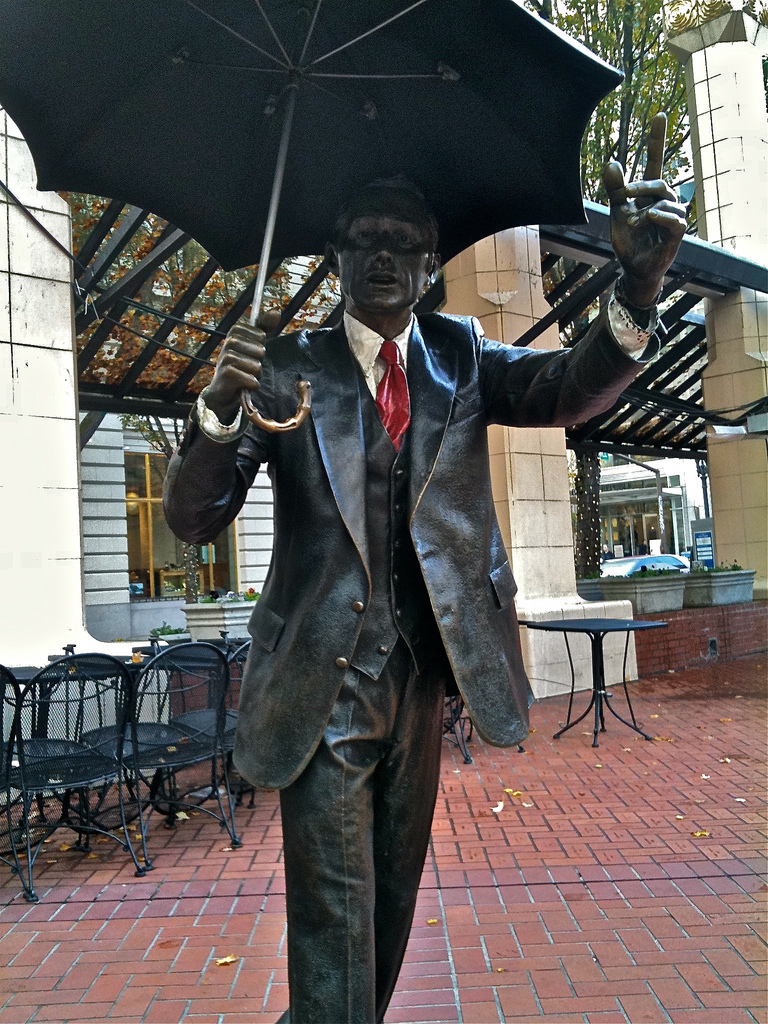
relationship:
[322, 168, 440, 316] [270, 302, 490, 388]
head above shoulder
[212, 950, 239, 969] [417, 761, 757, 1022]
leaf on ground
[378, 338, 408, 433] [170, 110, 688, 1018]
tie on statue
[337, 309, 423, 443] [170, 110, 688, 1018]
dress shirt painted on statue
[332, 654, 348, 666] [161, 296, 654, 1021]
button of dress shirt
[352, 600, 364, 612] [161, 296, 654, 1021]
button of dress shirt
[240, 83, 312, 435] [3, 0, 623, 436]
handle of an umbrella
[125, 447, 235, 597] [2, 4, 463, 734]
window of a building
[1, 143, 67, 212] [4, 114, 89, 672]
tile in a wall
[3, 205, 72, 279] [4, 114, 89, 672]
tile in a wall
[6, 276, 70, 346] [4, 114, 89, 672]
tile in a wall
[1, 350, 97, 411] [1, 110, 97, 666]
tile in a wall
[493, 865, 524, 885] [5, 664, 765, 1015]
brick in a sidewalk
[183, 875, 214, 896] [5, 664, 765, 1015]
brick in a sidewalk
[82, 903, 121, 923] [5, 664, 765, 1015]
brick in a sidewalk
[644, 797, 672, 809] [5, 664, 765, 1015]
brick in a sidewalk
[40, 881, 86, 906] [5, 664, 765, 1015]
brick in a sidewalk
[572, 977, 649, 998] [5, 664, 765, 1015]
brick in a sidewalk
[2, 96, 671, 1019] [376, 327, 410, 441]
statue wearing a tie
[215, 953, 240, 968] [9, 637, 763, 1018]
leaf on ground